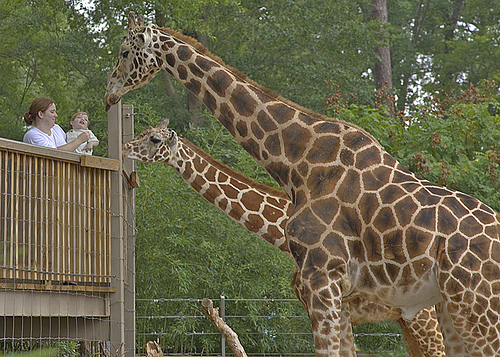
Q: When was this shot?
A: Daytime.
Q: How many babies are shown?
A: 1.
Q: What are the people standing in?
A: Platform.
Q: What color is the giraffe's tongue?
A: Black.